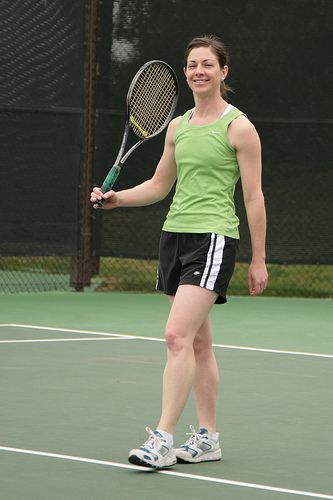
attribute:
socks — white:
[204, 429, 219, 439]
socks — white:
[155, 428, 173, 445]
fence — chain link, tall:
[8, 7, 322, 252]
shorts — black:
[155, 227, 241, 306]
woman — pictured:
[91, 33, 274, 287]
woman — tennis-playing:
[85, 33, 296, 470]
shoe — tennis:
[173, 427, 221, 462]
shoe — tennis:
[127, 429, 178, 470]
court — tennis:
[1, 292, 331, 498]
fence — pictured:
[0, 0, 332, 298]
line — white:
[198, 232, 226, 290]